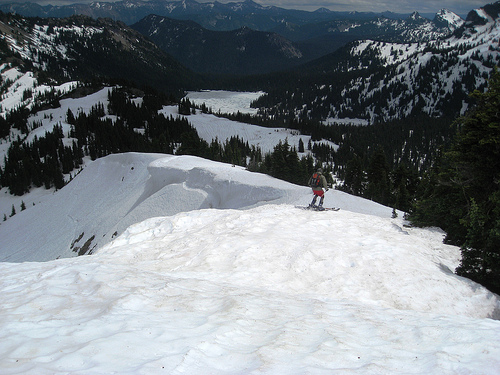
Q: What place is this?
A: It is a field.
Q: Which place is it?
A: It is a field.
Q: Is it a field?
A: Yes, it is a field.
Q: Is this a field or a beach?
A: It is a field.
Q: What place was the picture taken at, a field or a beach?
A: It was taken at a field.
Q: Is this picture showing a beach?
A: No, the picture is showing a field.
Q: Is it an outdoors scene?
A: Yes, it is outdoors.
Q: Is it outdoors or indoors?
A: It is outdoors.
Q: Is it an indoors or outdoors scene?
A: It is outdoors.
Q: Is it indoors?
A: No, it is outdoors.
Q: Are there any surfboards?
A: No, there are no surfboards.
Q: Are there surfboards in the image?
A: No, there are no surfboards.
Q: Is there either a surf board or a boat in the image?
A: No, there are no surfboards or boats.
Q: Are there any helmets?
A: No, there are no helmets.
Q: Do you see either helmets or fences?
A: No, there are no helmets or fences.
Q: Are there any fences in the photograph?
A: No, there are no fences.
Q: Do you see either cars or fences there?
A: No, there are no fences or cars.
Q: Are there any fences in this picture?
A: No, there are no fences.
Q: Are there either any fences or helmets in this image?
A: No, there are no fences or helmets.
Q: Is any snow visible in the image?
A: Yes, there is snow.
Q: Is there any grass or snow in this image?
A: Yes, there is snow.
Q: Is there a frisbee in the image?
A: No, there are no frisbees.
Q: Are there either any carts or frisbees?
A: No, there are no frisbees or carts.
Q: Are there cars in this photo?
A: No, there are no cars.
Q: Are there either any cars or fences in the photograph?
A: No, there are no cars or fences.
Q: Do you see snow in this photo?
A: Yes, there is snow.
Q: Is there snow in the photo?
A: Yes, there is snow.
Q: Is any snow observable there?
A: Yes, there is snow.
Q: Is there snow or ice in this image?
A: Yes, there is snow.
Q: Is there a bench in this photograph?
A: No, there are no benches.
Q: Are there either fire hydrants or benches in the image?
A: No, there are no benches or fire hydrants.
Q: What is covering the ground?
A: The snow is covering the ground.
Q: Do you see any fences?
A: No, there are no fences.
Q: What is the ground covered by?
A: The ground is covered by the snow.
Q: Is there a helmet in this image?
A: No, there are no helmets.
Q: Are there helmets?
A: No, there are no helmets.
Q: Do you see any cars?
A: No, there are no cars.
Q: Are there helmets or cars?
A: No, there are no cars or helmets.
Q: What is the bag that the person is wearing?
A: The bag is a backpack.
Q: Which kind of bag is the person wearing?
A: The person is wearing a backpack.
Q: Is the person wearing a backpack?
A: Yes, the person is wearing a backpack.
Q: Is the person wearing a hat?
A: No, the person is wearing a backpack.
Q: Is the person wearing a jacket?
A: Yes, the person is wearing a jacket.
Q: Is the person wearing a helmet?
A: No, the person is wearing a jacket.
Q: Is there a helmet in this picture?
A: No, there are no helmets.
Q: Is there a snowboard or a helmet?
A: No, there are no helmets or snowboards.